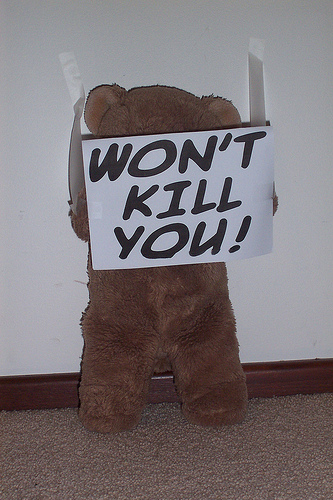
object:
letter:
[215, 176, 242, 211]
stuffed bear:
[68, 83, 279, 433]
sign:
[80, 127, 272, 271]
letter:
[88, 142, 133, 183]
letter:
[127, 140, 177, 177]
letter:
[178, 136, 217, 175]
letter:
[114, 224, 145, 259]